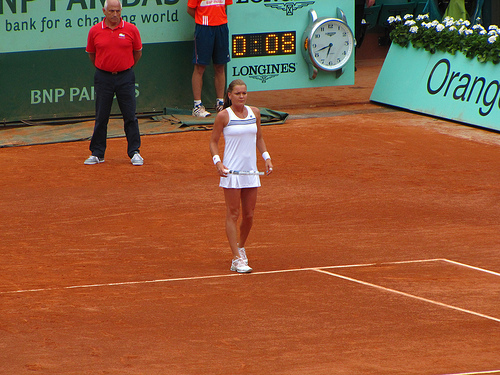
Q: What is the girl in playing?
A: Tennis.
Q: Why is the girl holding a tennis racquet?
A: She is playing tennis.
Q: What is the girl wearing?
A: A tennis dress.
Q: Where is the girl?
A: At a tennis court.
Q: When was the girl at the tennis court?
A: While she was playing tennis.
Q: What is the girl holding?
A: A tennis racquet.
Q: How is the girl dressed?
A: Like a tennis player.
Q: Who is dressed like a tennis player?
A: The girl.